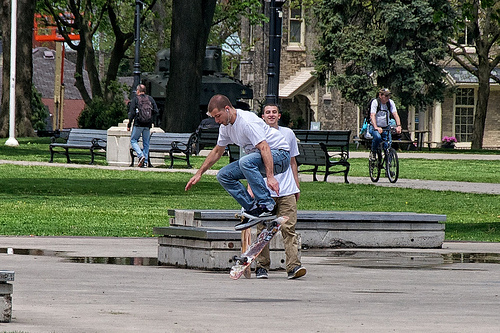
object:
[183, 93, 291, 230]
skateboarder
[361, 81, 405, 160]
man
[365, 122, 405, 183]
bicycle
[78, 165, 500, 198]
sidewalk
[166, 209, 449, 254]
benches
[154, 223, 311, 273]
benches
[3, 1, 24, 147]
post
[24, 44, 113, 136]
building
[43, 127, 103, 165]
bench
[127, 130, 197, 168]
bench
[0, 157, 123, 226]
lawn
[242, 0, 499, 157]
building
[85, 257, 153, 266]
water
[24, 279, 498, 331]
concrete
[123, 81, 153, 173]
man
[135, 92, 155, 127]
backpack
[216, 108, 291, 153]
t-shirt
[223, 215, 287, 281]
skateboard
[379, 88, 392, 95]
cap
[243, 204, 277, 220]
shoes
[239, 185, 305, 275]
pants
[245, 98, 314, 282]
man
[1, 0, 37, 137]
tree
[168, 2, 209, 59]
trunk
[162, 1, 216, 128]
tree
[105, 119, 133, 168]
pedestal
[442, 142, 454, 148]
pot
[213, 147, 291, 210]
jeans